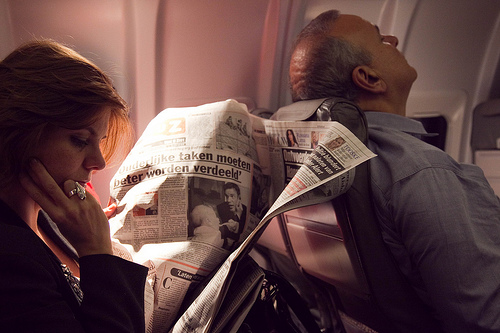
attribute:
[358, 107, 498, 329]
shirt — collared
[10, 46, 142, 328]
woman — reading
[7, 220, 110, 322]
jacket — black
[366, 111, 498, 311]
shirt — gray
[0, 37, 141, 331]
woman — wearing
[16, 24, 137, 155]
hair — red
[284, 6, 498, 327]
man — sleeping